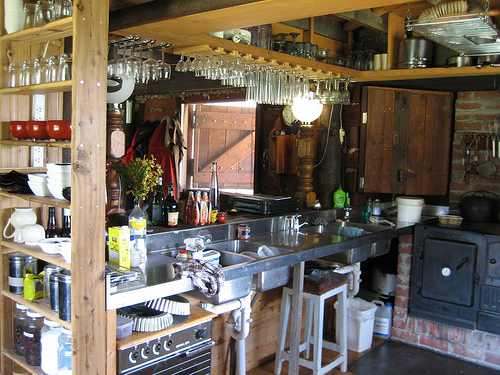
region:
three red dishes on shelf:
[10, 119, 70, 139]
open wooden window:
[187, 100, 254, 193]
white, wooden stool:
[276, 280, 350, 372]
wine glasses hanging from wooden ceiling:
[111, 33, 171, 82]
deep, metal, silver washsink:
[164, 240, 290, 304]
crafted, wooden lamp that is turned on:
[290, 93, 322, 205]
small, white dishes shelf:
[27, 162, 74, 197]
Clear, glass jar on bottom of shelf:
[14, 305, 39, 365]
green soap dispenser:
[334, 186, 346, 207]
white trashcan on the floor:
[336, 298, 372, 352]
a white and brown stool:
[283, 267, 352, 371]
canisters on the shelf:
[3, 250, 72, 317]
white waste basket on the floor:
[328, 295, 385, 366]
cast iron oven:
[402, 224, 489, 336]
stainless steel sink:
[185, 220, 308, 311]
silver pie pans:
[118, 291, 193, 343]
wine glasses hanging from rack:
[178, 40, 341, 133]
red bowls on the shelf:
[8, 108, 77, 160]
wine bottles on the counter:
[178, 164, 231, 234]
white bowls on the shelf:
[20, 160, 75, 214]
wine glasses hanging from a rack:
[104, 33, 177, 87]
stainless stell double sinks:
[173, 237, 313, 303]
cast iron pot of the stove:
[454, 180, 498, 234]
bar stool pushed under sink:
[283, 267, 365, 372]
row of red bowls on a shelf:
[1, 104, 79, 153]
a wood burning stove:
[404, 194, 496, 331]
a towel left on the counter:
[157, 250, 236, 306]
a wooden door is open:
[166, 89, 253, 205]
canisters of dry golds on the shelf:
[1, 300, 73, 372]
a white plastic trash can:
[323, 296, 384, 362]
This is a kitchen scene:
[4, 22, 496, 367]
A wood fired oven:
[408, 211, 497, 331]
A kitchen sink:
[179, 212, 302, 299]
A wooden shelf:
[0, 5, 105, 373]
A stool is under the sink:
[272, 244, 355, 373]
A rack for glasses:
[170, 37, 356, 122]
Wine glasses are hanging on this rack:
[106, 28, 176, 93]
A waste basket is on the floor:
[337, 296, 380, 353]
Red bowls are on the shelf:
[3, 108, 77, 150]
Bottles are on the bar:
[162, 162, 222, 230]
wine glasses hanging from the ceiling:
[115, 29, 175, 82]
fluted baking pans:
[127, 292, 195, 334]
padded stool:
[274, 265, 353, 372]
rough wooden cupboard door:
[353, 84, 462, 206]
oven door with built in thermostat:
[407, 239, 495, 313]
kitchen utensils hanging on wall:
[446, 129, 498, 187]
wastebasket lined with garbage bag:
[329, 292, 379, 357]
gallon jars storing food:
[2, 300, 72, 374]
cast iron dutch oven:
[456, 183, 498, 228]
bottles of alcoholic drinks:
[150, 163, 225, 227]